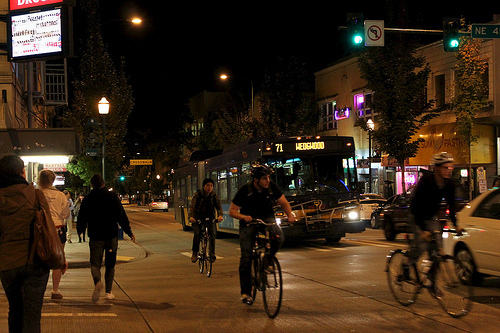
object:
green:
[450, 38, 460, 48]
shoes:
[91, 282, 115, 303]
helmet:
[249, 164, 274, 178]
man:
[404, 152, 466, 298]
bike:
[384, 229, 474, 319]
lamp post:
[102, 114, 108, 185]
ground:
[416, 160, 457, 192]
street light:
[97, 96, 110, 115]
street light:
[366, 119, 375, 131]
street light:
[156, 174, 161, 180]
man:
[187, 178, 225, 263]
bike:
[189, 217, 222, 277]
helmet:
[429, 151, 456, 165]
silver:
[435, 155, 449, 159]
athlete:
[28, 169, 69, 300]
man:
[228, 163, 296, 304]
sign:
[364, 20, 385, 46]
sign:
[295, 141, 325, 151]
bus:
[173, 135, 367, 247]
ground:
[313, 127, 377, 185]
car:
[440, 184, 500, 285]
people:
[76, 174, 136, 302]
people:
[0, 153, 63, 333]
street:
[0, 189, 500, 332]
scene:
[16, 79, 500, 333]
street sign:
[470, 24, 499, 39]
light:
[354, 35, 364, 43]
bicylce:
[241, 217, 293, 319]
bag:
[33, 188, 66, 270]